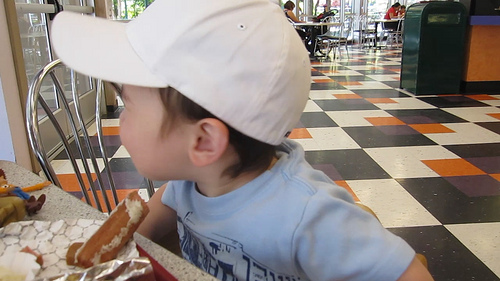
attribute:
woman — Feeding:
[284, 4, 313, 47]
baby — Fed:
[310, 0, 335, 22]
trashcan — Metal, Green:
[398, 0, 473, 96]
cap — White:
[46, 1, 317, 149]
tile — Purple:
[375, 120, 420, 144]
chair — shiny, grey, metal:
[12, 54, 169, 242]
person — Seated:
[39, 1, 436, 279]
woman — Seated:
[382, 2, 403, 35]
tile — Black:
[428, 177, 458, 214]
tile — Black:
[306, 143, 391, 180]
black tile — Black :
[338, 124, 440, 149]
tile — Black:
[375, 117, 468, 193]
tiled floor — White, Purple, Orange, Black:
[348, 95, 498, 190]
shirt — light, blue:
[170, 181, 417, 279]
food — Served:
[0, 221, 145, 275]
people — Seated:
[387, 2, 401, 23]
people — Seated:
[284, 3, 300, 20]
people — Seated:
[38, 3, 435, 268]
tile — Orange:
[350, 100, 476, 208]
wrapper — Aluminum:
[0, 211, 153, 279]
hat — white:
[45, 6, 309, 148]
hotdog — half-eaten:
[71, 191, 151, 270]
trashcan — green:
[393, 0, 468, 101]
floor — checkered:
[347, 98, 499, 193]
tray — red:
[134, 240, 179, 276]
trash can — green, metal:
[400, 1, 468, 93]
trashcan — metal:
[400, 3, 472, 107]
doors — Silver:
[13, 2, 113, 162]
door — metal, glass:
[9, 0, 104, 177]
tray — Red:
[117, 240, 199, 279]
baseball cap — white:
[51, 4, 302, 150]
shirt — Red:
[384, 5, 400, 16]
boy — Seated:
[34, 8, 390, 278]